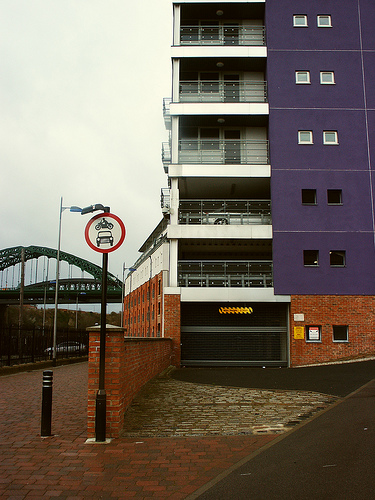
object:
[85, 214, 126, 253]
sign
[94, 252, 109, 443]
pole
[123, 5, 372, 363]
building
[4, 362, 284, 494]
ground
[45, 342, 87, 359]
car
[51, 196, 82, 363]
light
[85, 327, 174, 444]
wall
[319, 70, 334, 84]
windows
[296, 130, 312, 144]
windows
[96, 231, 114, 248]
car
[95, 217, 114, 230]
motorcycle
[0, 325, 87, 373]
garage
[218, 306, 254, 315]
sign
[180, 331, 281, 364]
door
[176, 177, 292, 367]
garage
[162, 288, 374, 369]
first floor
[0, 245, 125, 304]
bridge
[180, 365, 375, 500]
ramp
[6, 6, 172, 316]
sky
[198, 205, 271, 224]
car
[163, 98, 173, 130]
balcony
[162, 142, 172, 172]
balcony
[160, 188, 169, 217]
balcony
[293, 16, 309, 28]
window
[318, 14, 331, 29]
window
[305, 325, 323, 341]
window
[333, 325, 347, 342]
window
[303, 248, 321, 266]
window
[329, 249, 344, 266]
window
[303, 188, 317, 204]
window